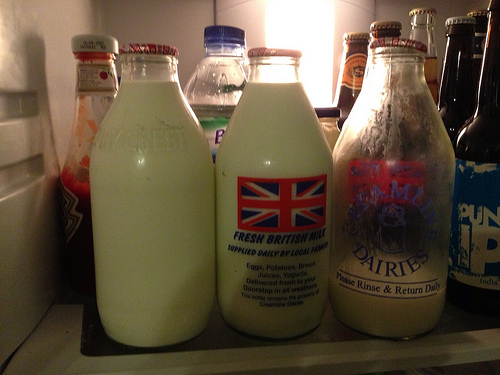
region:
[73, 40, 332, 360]
Two full bottles of milk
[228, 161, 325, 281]
British flag on milk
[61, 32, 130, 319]
Ketchup behind milk bottle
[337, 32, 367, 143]
Brown bottle behind milk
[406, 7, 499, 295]
four beer bottles together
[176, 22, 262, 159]
Bottle with blue cap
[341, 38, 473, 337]
Bottle is almost empty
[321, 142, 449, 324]
Bottle says dairies in blue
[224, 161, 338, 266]
Flag is blue and red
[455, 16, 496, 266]
White and blue on brown bottle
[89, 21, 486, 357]
three bottles of milk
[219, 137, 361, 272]
fresh british milk on bottle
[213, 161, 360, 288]
the union jack flag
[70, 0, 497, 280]
the milk is in the fridge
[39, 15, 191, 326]
a bottle of ketchup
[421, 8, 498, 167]
a bottle of beer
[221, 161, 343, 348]
the text is blue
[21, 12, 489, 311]
glass bottles in a fridge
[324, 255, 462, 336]
please rinse and return daily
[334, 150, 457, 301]
the logo is blue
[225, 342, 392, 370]
the shelf is white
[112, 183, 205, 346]
the liduid is white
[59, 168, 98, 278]
the ketchup is red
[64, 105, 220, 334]
ketchup is behind milk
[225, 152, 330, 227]
flag is on bottle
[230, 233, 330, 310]
the letters are black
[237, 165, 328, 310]
flag above the letters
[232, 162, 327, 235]
flag is for Great Britain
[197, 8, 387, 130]
light behind the bottles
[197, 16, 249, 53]
the cap is blue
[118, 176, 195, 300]
The milk is green.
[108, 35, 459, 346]
Three bottles of milk.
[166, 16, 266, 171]
A bottle of water in the background.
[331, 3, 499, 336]
A lot of beer in the background.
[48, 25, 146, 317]
A bottle of ketchup.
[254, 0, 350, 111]
A refrigerator light.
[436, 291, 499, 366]
The shelf is made of glass and plastic.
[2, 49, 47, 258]
The refrigerator is white on the sides.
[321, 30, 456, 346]
This bottle of milk is almost gone.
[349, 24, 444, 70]
The lid is not on the bottle well.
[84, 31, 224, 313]
bottle with red top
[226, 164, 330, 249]
red, white, and blue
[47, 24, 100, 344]
catsup bottle on shelf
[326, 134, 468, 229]
red label on bottle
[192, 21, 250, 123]
blue cap on container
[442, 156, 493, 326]
blue and white label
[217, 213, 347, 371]
blue writing on bottle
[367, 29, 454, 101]
cap askew on bottle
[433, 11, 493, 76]
metal cap on bottle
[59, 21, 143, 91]
white cap on bottle